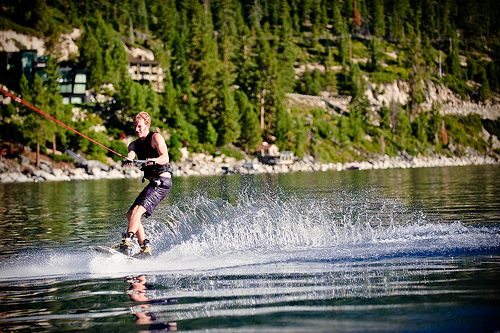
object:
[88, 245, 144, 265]
ski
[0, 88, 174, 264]
skiing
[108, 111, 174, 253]
man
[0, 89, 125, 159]
line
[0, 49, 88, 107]
building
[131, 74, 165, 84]
wooden deck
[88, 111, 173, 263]
man skiing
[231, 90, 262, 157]
pine trees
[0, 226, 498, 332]
ripples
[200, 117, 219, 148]
pine trees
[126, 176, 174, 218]
swim trunks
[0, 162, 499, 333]
wake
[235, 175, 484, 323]
large body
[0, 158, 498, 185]
rocky shoreline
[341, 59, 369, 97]
trees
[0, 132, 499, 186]
shore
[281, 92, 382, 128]
houses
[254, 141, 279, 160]
small house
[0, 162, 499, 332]
body/water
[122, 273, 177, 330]
reflection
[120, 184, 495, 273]
splashes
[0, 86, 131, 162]
rope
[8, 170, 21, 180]
stones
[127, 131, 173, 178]
clothes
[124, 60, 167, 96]
buildings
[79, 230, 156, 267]
surfboard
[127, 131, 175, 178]
top